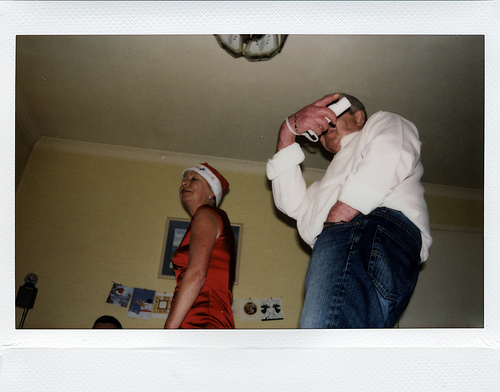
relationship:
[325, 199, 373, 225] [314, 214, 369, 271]
hand in pocket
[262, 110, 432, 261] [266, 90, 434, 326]
shirt on man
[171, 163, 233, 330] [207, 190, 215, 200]
woman wearing earring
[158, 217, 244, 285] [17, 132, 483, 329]
picture frame on wall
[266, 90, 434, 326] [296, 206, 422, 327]
man wearing jeans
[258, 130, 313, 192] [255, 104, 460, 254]
cuff on shirt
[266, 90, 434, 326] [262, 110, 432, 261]
man has shirt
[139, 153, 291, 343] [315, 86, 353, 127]
people playing game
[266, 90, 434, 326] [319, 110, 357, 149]
man obscuring face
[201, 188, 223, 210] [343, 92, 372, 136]
earring in ear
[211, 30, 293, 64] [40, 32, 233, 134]
light on ceiling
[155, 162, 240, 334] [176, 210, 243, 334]
woman wearing red dress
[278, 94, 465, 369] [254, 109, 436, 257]
man wearing white shirt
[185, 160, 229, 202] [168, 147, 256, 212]
hat on head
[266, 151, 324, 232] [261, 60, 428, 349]
sleeve of man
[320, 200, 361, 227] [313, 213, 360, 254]
hand in man's pocket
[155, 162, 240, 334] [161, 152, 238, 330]
woman in a santa outfit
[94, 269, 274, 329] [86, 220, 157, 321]
pictures on wall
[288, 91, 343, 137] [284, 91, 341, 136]
remote control in a man's hand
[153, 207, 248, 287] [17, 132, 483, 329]
picture hanging from wall